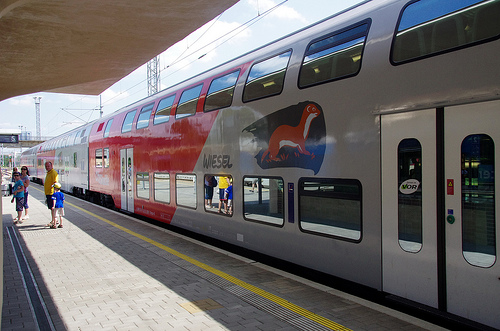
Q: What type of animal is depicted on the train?
A: Weasel.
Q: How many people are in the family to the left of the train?
A: Four.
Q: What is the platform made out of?
A: Stone.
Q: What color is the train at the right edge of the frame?
A: Silver.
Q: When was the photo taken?
A: Daytime.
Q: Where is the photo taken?
A: Train station.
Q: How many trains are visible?
A: One.